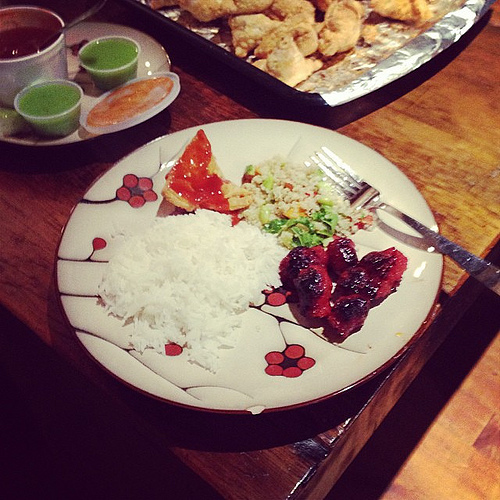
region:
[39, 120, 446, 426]
the plate of food is on the table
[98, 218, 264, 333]
rice is on the plate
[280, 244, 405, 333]
meat is on the plate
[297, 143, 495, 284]
a fork is on the plate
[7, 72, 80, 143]
the sauce is green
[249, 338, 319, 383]
the flower is red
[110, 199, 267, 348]
the rice is white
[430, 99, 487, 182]
the table is brown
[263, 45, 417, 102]
the food is on foils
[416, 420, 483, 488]
the floor is wooden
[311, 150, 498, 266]
silver fork on plate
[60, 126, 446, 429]
white plate on table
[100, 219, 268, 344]
white rice on plate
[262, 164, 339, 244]
green lettuce on place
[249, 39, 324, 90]
pizza rolls on pan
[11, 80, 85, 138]
guacamole in small cup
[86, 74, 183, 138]
top of sauce's container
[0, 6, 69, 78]
sauce in a container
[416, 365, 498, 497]
wood flooring on ground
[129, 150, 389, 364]
food on the plate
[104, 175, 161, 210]
red rose design on plate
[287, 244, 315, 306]
burnt glaze on food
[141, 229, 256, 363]
white rice on the dish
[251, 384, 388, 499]
table is made of wood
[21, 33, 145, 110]
two green sauces in cups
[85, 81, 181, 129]
lid with sauce on it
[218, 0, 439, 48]
food on tin foil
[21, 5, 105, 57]
spoon in cup of sauce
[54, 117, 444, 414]
a round ceramic plate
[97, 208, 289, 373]
white rice on the plate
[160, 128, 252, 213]
a fried wonton with sauce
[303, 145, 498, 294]
a metal fork on the plate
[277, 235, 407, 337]
some meat on the plate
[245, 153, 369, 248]
some vegetables on the plate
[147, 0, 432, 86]
fried wontons on a pan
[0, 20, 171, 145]
a small round plate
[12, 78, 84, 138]
a plastic container of green sauce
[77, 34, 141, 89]
a plastic container of green sauce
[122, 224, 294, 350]
the rice is white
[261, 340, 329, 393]
drawings are on the plate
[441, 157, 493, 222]
the table is brown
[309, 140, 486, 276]
the fork is silver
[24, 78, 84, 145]
green liquid is in the cup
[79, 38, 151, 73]
the cup is plastic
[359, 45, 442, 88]
foilpaper is on the tray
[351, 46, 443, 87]
the foilpaper is silver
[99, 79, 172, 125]
sauce is on the lid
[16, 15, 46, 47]
sauce is in the cup